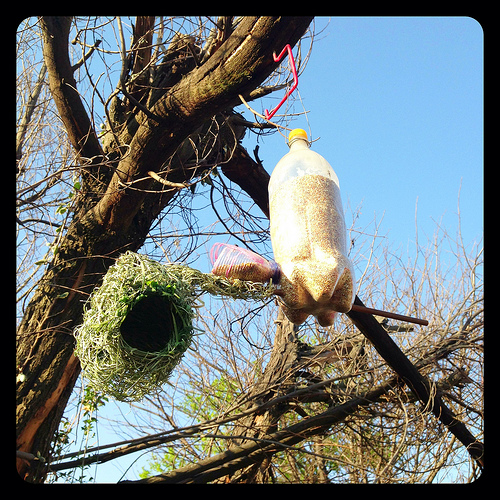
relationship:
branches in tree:
[68, 27, 171, 112] [15, 13, 486, 486]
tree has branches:
[15, 13, 486, 486] [366, 211, 467, 314]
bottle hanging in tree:
[266, 129, 355, 327] [15, 13, 486, 486]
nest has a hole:
[73, 250, 197, 404] [118, 290, 182, 356]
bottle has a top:
[266, 129, 355, 327] [285, 129, 308, 144]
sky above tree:
[15, 16, 486, 485] [15, 13, 486, 486]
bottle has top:
[266, 129, 355, 327] [285, 129, 308, 144]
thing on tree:
[261, 43, 301, 120] [15, 13, 486, 486]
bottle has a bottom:
[266, 129, 355, 327] [284, 293, 354, 326]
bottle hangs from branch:
[266, 129, 355, 327] [83, 13, 316, 235]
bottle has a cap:
[266, 129, 355, 327] [285, 129, 308, 144]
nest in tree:
[73, 250, 197, 404] [15, 13, 486, 486]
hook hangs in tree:
[261, 43, 301, 120] [15, 13, 486, 486]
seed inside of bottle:
[266, 174, 356, 327] [266, 129, 355, 327]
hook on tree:
[261, 43, 301, 120] [15, 13, 486, 486]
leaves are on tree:
[58, 177, 351, 483] [15, 13, 486, 486]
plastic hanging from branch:
[266, 129, 355, 327] [83, 13, 316, 235]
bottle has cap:
[266, 129, 355, 327] [285, 129, 308, 144]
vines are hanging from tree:
[15, 19, 483, 484] [15, 13, 486, 486]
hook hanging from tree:
[261, 43, 301, 120] [15, 13, 486, 486]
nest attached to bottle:
[73, 250, 197, 404] [266, 129, 355, 327]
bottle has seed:
[266, 129, 355, 327] [266, 174, 356, 327]